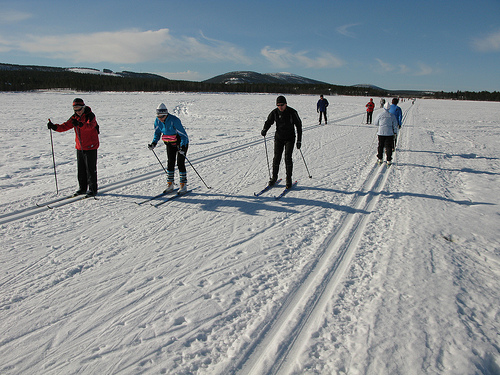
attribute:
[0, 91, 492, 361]
snow — white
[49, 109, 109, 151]
coat — red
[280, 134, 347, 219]
pole — black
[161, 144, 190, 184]
pants — black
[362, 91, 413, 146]
jacket — white